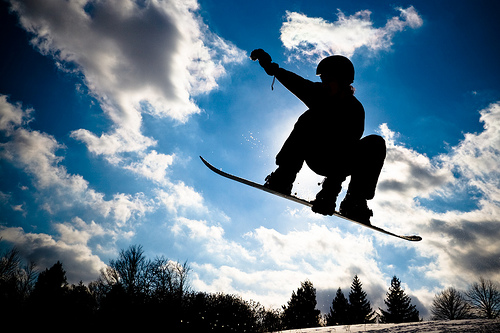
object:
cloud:
[11, 2, 251, 131]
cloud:
[363, 102, 500, 294]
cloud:
[278, 4, 425, 69]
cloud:
[153, 223, 444, 320]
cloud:
[1, 215, 115, 294]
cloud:
[65, 124, 160, 165]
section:
[13, 1, 236, 125]